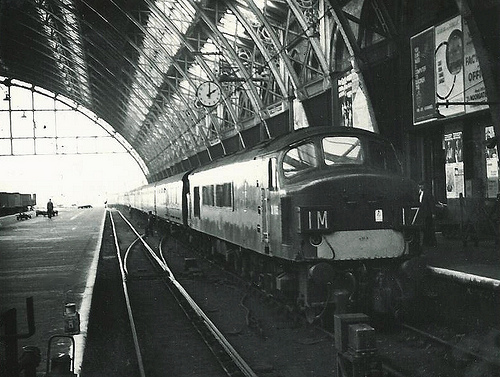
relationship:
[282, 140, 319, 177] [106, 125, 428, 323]
window on train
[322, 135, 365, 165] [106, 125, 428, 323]
window on train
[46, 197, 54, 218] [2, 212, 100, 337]
person on concrete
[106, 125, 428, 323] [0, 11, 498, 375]
train in station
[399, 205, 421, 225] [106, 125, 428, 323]
numbers on train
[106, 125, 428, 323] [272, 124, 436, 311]
train has front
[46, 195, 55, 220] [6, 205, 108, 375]
person walking on ground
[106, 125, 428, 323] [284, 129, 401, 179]
train has window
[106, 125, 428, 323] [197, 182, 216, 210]
train has window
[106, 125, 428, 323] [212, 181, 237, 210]
train has window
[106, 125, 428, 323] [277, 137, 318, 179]
train has window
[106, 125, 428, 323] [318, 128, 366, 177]
train has window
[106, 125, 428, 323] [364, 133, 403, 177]
train has window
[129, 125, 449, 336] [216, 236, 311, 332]
train has wheels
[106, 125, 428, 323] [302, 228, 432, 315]
train has bumper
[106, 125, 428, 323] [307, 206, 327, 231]
train has letters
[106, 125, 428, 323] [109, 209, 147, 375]
train on train tracks